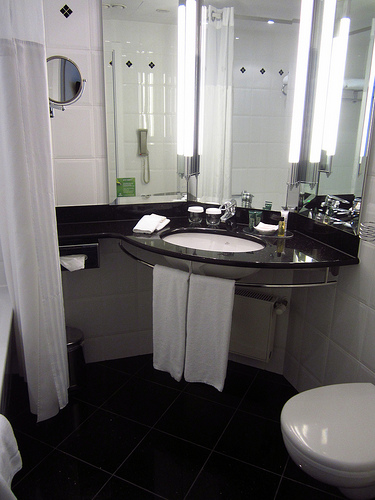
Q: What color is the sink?
A: Black.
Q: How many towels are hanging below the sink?
A: 2.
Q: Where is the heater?
A: Under the sink.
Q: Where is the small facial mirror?
A: On the left.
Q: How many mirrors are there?
A: 4.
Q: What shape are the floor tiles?
A: Square.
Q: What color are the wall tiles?
A: White.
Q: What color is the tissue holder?
A: Black.